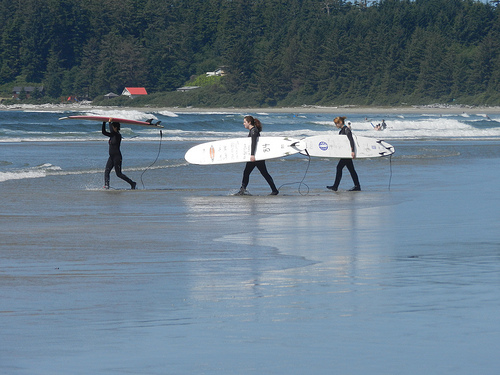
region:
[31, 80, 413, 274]
three surfers on a beach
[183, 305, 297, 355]
water reflecting on the sand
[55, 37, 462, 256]
red roof in background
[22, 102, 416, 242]
the wetsuits are black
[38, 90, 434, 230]
surfer in the middle is woman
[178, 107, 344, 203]
she has a pony tail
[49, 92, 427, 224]
three surfboards have tethers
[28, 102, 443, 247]
the surfboards are white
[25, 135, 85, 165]
the water is blue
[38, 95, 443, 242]
the sport of surfing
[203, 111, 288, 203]
surfer walking in water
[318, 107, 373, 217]
surfer walking in water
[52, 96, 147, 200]
surfer walking in water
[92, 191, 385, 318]
waves of water receeding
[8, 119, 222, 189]
water has whitecapped waves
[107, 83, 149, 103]
building with orange roof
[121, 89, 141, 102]
white building by trees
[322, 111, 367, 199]
surfer with black wetsuit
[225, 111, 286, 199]
surfer with black wetsuit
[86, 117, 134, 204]
surfer with black wetsuit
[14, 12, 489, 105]
green evergreens by water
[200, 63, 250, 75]
white rocks by trees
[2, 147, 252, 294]
blue and grey water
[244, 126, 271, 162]
arm of surfer over surfboard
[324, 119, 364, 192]
surfer carrying surfboard to water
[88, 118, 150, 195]
two arms holding up surfboard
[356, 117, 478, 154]
white waves crashing over swimmer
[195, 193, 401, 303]
reflection on the water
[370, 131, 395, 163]
black fin on surfboard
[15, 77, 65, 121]
green grass by trees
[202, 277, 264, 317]
part of a sea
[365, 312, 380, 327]
part of a lake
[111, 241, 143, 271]
ripples of water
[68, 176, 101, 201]
section of the ocean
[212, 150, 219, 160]
a white surf board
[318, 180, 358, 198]
legs of a woman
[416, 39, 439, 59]
part of a forest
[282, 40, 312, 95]
branches of a forest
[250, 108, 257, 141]
head of a girl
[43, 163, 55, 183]
wave of an ocean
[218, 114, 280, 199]
surfer in long brown hair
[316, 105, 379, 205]
surfer in short brown hair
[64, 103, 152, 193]
surfer carrying surfboard over head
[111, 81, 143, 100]
orange roof over building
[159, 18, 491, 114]
green trees beside water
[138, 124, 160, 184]
chord from surfboard to surfer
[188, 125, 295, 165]
surfboard is white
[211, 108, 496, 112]
grey rocky beach by water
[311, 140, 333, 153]
blue circle on surfboard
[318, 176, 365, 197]
legs of a surfer